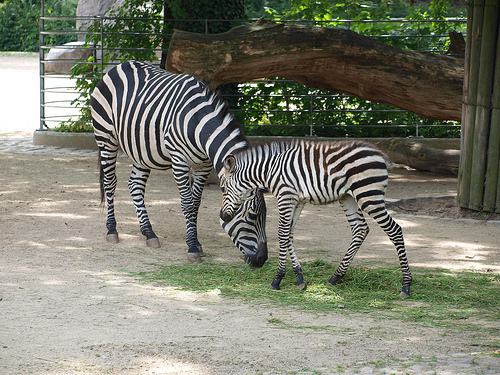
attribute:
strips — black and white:
[142, 125, 439, 248]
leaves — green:
[372, 99, 447, 177]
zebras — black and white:
[79, 57, 422, 318]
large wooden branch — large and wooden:
[163, 15, 470, 133]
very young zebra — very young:
[204, 138, 420, 308]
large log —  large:
[204, 105, 499, 194]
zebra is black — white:
[85, 60, 270, 288]